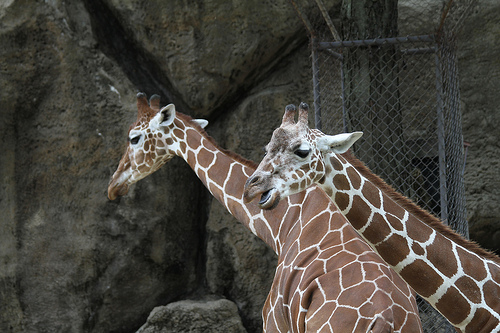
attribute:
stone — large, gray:
[144, 295, 239, 330]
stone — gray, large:
[0, 0, 303, 331]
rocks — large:
[15, 5, 305, 126]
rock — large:
[9, 16, 324, 331]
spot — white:
[106, 83, 121, 100]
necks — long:
[180, 130, 495, 325]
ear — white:
[315, 127, 364, 152]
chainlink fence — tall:
[279, 1, 476, 331]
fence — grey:
[296, 47, 483, 245]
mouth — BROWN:
[104, 173, 136, 207]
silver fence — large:
[291, 0, 472, 237]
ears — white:
[324, 126, 364, 154]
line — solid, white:
[393, 230, 450, 277]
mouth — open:
[249, 172, 271, 215]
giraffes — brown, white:
[108, 96, 488, 330]